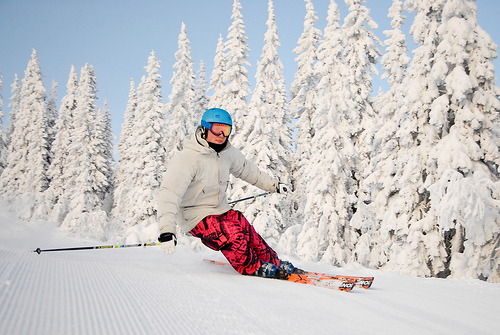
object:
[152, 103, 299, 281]
man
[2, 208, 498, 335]
mountain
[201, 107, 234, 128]
helmet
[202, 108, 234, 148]
head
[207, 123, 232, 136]
goggles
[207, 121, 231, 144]
face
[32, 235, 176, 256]
ski pole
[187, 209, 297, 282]
pants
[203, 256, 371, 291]
skis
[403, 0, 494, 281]
trees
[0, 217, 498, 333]
snow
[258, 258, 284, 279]
boots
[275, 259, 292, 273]
buckles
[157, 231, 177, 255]
gloves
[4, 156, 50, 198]
bottom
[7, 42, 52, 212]
tree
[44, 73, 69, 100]
cloud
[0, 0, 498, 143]
sky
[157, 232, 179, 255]
hand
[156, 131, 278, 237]
coat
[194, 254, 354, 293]
board